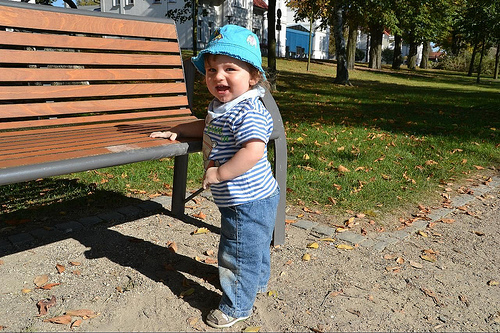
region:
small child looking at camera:
[187, 20, 283, 330]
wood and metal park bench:
[0, 3, 290, 244]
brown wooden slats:
[0, 5, 220, 162]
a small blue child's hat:
[190, 23, 270, 72]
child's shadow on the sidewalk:
[68, 217, 225, 312]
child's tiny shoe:
[205, 300, 253, 327]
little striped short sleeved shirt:
[201, 95, 279, 211]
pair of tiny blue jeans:
[213, 192, 278, 324]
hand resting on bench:
[148, 121, 189, 147]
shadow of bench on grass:
[1, 181, 162, 258]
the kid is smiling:
[204, 75, 283, 125]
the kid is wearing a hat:
[187, 13, 280, 139]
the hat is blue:
[183, 11, 276, 99]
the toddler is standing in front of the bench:
[129, 14, 311, 305]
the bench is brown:
[27, 12, 138, 160]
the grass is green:
[301, 100, 412, 185]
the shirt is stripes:
[182, 93, 291, 225]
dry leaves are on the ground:
[292, 99, 456, 207]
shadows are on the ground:
[275, 58, 442, 131]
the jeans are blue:
[189, 191, 306, 304]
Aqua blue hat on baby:
[188, 23, 268, 63]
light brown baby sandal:
[208, 302, 256, 326]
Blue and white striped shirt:
[200, 96, 277, 209]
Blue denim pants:
[212, 192, 283, 314]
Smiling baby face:
[196, 52, 253, 104]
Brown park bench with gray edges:
[0, 4, 204, 212]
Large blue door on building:
[287, 22, 314, 57]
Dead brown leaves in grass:
[287, 86, 484, 193]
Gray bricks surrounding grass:
[288, 205, 491, 254]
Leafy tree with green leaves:
[309, 0, 399, 87]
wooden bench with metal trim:
[0, 1, 200, 222]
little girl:
[195, 20, 285, 325]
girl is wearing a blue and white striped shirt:
[195, 95, 280, 205]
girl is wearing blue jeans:
[202, 183, 283, 308]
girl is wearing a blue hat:
[187, 23, 274, 77]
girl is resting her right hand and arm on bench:
[145, 101, 226, 168]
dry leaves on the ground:
[30, 260, 105, 330]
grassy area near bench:
[83, 15, 491, 231]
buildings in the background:
[96, 0, 441, 72]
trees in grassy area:
[284, 0, 496, 94]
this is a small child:
[199, 21, 266, 328]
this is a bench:
[0, 11, 180, 172]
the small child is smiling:
[207, 61, 243, 104]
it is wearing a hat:
[193, 27, 270, 57]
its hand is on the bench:
[136, 117, 205, 139]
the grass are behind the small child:
[309, 79, 476, 211]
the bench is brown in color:
[0, 16, 181, 169]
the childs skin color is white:
[206, 60, 247, 95]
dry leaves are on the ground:
[426, 185, 492, 257]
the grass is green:
[329, 88, 461, 173]